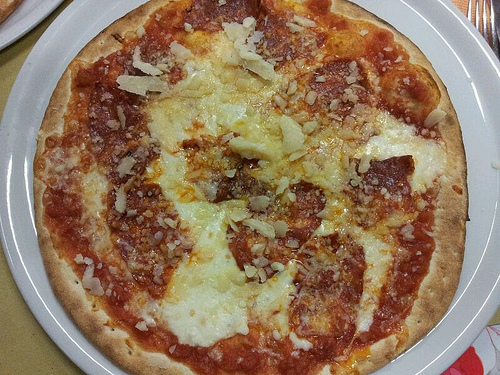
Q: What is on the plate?
A: Pizza.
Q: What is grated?
A: Cheese.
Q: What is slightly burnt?
A: The crust.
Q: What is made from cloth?
A: The tablecloth.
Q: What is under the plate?
A: Tablecloth.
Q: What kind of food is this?
A: Pizza.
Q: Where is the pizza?
A: On the plate.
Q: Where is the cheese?
A: On the pizza.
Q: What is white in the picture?
A: A plate.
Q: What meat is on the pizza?
A: Pepperoni.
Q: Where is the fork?
A: By the plate.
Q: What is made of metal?
A: Fork.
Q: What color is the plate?
A: White.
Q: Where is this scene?
A: In a restaurant.